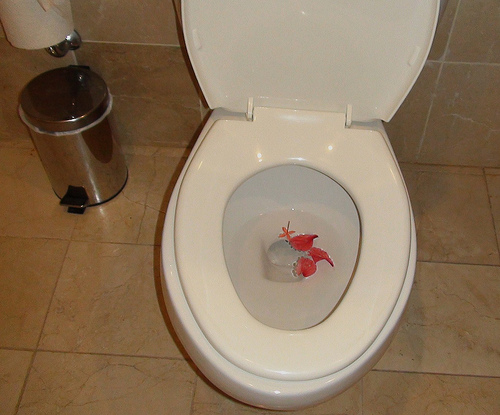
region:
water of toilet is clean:
[232, 195, 353, 329]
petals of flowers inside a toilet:
[236, 182, 347, 314]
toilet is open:
[149, 4, 445, 401]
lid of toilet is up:
[168, 0, 456, 130]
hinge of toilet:
[236, 97, 360, 134]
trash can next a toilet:
[11, 57, 138, 222]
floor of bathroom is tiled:
[3, 111, 490, 412]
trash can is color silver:
[9, 57, 142, 225]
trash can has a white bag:
[13, 65, 123, 150]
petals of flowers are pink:
[271, 213, 338, 282]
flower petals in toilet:
[278, 215, 338, 285]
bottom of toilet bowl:
[188, 111, 421, 363]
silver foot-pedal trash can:
[13, 70, 145, 212]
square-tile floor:
[26, 232, 186, 407]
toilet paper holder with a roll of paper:
[0, 0, 93, 57]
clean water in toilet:
[236, 210, 338, 307]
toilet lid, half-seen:
[175, 7, 450, 127]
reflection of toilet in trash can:
[73, 125, 136, 167]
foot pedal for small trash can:
[54, 180, 103, 219]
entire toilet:
[73, 0, 447, 404]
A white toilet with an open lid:
[167, 1, 430, 401]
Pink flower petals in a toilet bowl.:
[274, 210, 336, 282]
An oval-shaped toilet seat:
[180, 96, 410, 387]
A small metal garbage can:
[10, 62, 142, 222]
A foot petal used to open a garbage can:
[53, 180, 98, 227]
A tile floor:
[2, 222, 148, 411]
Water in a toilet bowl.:
[224, 188, 349, 316]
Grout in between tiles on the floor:
[50, 327, 150, 387]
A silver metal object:
[33, 26, 88, 59]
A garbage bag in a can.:
[13, 79, 122, 135]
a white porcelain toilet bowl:
[151, 102, 418, 402]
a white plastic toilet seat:
[166, 111, 411, 388]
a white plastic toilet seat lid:
[180, 0, 442, 116]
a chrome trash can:
[17, 63, 133, 218]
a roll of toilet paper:
[0, 0, 77, 60]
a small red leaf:
[276, 221, 295, 243]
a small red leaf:
[290, 231, 317, 251]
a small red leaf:
[304, 246, 335, 265]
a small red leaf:
[294, 256, 316, 278]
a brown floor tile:
[35, 235, 189, 357]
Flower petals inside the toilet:
[270, 213, 340, 282]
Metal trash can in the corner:
[18, 87, 132, 217]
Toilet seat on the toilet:
[177, 126, 392, 376]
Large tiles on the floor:
[28, 246, 166, 413]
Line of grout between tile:
[398, 351, 498, 383]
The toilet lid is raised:
[165, 1, 454, 93]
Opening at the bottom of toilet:
[265, 252, 312, 287]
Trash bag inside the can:
[14, 107, 96, 145]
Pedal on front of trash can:
[55, 189, 100, 230]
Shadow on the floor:
[402, 252, 431, 410]